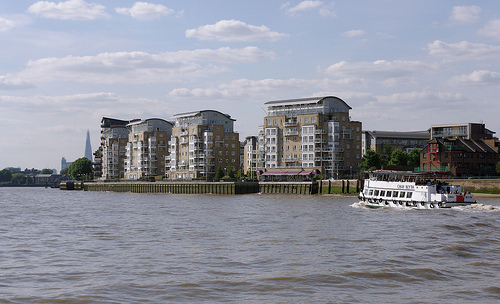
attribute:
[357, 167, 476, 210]
boat — white, tour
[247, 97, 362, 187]
apartment — tan, building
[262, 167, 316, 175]
awning — red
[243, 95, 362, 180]
building — tan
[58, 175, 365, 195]
boat dock — green